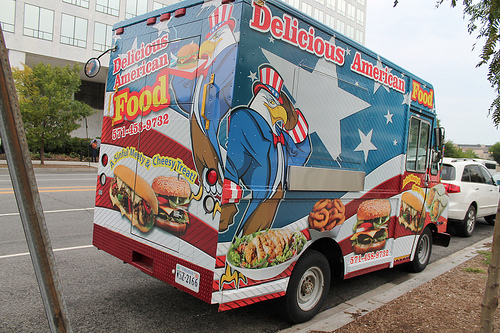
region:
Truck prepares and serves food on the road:
[83, 1, 453, 321]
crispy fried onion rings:
[300, 172, 346, 234]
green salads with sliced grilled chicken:
[222, 218, 318, 293]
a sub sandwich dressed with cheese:
[107, 165, 157, 233]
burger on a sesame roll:
[145, 185, 190, 228]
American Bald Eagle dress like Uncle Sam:
[187, 70, 309, 236]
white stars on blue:
[260, 46, 398, 156]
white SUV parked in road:
[438, 135, 498, 235]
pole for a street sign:
[0, 35, 66, 331]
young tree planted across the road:
[3, 53, 81, 174]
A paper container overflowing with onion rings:
[306, 195, 346, 242]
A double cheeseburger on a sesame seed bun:
[348, 197, 393, 257]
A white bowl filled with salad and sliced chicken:
[224, 225, 306, 284]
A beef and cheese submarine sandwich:
[107, 163, 159, 236]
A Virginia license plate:
[173, 261, 200, 295]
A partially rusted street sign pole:
[1, 22, 73, 332]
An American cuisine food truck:
[84, 0, 451, 322]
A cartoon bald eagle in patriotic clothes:
[217, 62, 312, 292]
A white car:
[440, 157, 499, 240]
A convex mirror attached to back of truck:
[83, 44, 120, 80]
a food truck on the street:
[91, 15, 484, 302]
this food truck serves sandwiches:
[100, 16, 317, 293]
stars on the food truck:
[253, 29, 405, 155]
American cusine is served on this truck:
[250, 2, 446, 109]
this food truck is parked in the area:
[68, 33, 488, 287]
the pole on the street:
[4, 72, 81, 329]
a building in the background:
[8, 12, 355, 152]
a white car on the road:
[413, 130, 499, 245]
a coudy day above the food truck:
[353, 8, 495, 165]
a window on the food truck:
[398, 101, 455, 189]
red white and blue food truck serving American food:
[87, 0, 451, 325]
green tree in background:
[17, 54, 93, 171]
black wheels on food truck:
[284, 226, 439, 323]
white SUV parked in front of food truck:
[436, 149, 499, 241]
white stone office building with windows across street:
[0, 0, 372, 168]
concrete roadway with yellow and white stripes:
[0, 158, 498, 328]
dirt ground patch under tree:
[338, 248, 499, 330]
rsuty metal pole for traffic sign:
[0, 45, 97, 328]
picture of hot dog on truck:
[104, 163, 159, 233]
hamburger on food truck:
[152, 167, 193, 233]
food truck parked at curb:
[49, 0, 458, 323]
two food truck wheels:
[281, 214, 436, 323]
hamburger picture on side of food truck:
[347, 188, 395, 272]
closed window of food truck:
[279, 50, 396, 202]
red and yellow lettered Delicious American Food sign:
[109, 28, 174, 124]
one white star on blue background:
[350, 120, 379, 163]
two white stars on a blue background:
[379, 103, 401, 153]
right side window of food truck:
[403, 108, 435, 183]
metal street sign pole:
[6, 38, 73, 330]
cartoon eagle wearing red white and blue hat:
[228, 59, 313, 227]